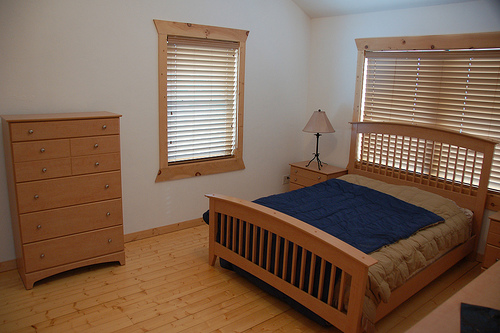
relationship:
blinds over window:
[362, 53, 499, 184] [359, 47, 499, 192]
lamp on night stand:
[305, 107, 334, 168] [290, 158, 348, 199]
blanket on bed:
[202, 180, 443, 255] [205, 123, 497, 331]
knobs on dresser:
[38, 147, 52, 175] [7, 111, 127, 289]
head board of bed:
[347, 115, 499, 201] [205, 123, 497, 331]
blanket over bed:
[202, 180, 443, 255] [205, 123, 497, 331]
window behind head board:
[359, 47, 499, 192] [347, 115, 499, 201]